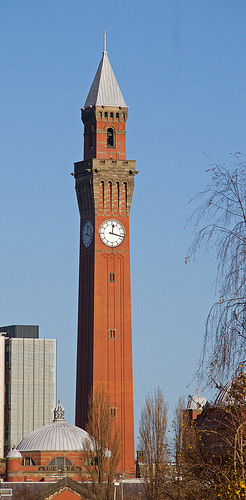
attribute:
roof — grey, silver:
[74, 37, 131, 112]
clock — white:
[91, 209, 123, 256]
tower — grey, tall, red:
[97, 220, 133, 249]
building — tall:
[75, 46, 146, 421]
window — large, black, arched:
[96, 122, 119, 153]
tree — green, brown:
[142, 382, 167, 475]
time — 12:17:
[101, 220, 124, 245]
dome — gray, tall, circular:
[21, 422, 94, 456]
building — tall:
[3, 326, 58, 420]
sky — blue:
[51, 25, 83, 42]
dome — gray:
[23, 421, 89, 443]